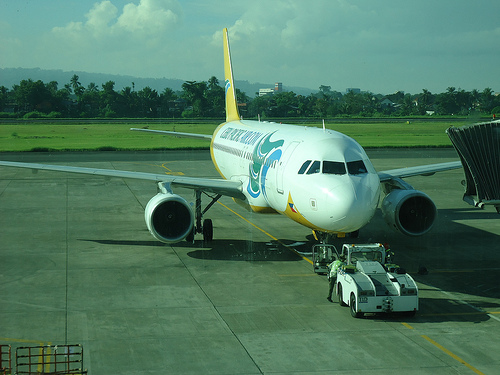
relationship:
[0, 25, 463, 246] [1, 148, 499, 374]
airplane sitting on tarmac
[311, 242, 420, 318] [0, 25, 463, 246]
vehicle tows airplane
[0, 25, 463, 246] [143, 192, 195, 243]
airplane has jet engine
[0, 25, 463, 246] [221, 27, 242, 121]
airplane has tail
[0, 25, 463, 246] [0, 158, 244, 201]
airplane has wing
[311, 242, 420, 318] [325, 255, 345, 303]
vehicle has driver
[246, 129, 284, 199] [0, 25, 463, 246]
logo on side of airplane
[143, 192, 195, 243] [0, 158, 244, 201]
jet engine on side of wing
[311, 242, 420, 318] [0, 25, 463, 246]
vehicle in front of airplane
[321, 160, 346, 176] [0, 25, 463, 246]
window in front of airplane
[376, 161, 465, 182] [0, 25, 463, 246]
wing on side of airplane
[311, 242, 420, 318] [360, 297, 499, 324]
vehicle has shadow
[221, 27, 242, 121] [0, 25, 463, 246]
tail on back of airplane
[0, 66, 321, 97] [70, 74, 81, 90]
mountain behind tree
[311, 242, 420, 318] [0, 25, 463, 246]
vehicle going to pull airplane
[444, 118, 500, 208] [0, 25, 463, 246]
passenger bridge will attach to airplane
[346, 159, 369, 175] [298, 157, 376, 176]
window in front of cockpit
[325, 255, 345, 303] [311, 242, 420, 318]
driver getting into vehicle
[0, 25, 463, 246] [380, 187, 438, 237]
airplane has jet engine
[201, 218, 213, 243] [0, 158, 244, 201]
wheel under wing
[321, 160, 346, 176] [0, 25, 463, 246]
window on front of airplane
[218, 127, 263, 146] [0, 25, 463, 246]
lettering on side of airplane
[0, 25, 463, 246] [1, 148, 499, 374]
airplane parked on tarmac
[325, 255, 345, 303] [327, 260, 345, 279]
driver wearing shirt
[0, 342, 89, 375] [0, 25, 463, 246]
luggage cart in front of airplane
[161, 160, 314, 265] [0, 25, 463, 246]
line under airplane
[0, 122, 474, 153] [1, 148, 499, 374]
area behind tarmac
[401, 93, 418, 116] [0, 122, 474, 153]
tree behind area